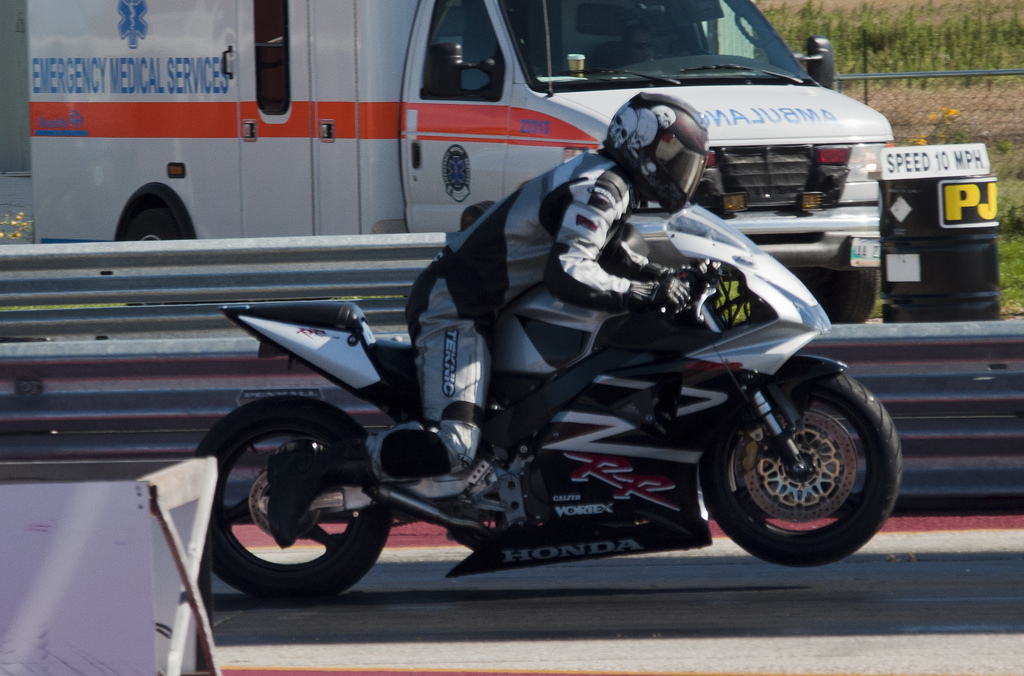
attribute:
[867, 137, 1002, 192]
signs — outside the track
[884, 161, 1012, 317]
barrel — black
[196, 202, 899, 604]
bike — black and white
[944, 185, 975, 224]
letter — yellow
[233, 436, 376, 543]
boot — black 